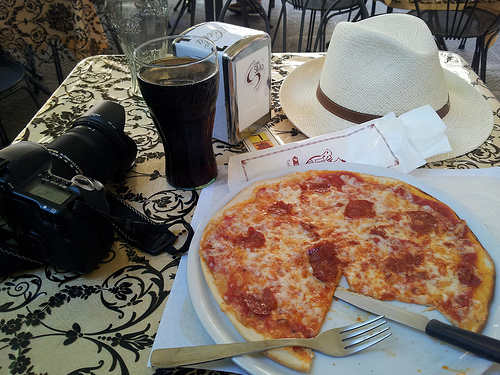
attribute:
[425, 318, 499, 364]
handle — black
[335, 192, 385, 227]
sign — red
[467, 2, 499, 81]
chair — black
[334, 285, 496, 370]
knife — silver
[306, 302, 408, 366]
fork prong — silver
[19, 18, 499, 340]
table — white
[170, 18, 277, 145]
napkin holder — silver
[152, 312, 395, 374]
fork — silver